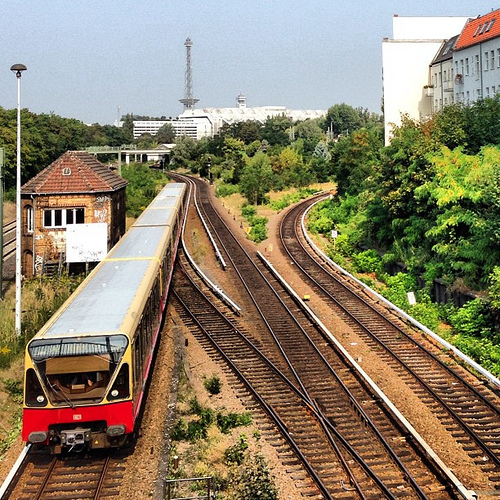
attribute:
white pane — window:
[40, 205, 89, 227]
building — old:
[30, 149, 108, 254]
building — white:
[117, 98, 334, 141]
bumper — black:
[101, 415, 126, 437]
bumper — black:
[103, 423, 130, 442]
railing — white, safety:
[279, 186, 439, 494]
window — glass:
[66, 186, 103, 233]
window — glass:
[30, 360, 137, 402]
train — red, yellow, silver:
[18, 180, 195, 459]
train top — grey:
[36, 225, 168, 336]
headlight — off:
[32, 395, 47, 407]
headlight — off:
[105, 385, 122, 400]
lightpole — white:
[14, 72, 26, 342]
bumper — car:
[25, 430, 49, 450]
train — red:
[1, 282, 131, 447]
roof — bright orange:
[454, 10, 498, 50]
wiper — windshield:
[42, 373, 74, 410]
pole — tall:
[12, 52, 32, 351]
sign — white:
[45, 203, 140, 263]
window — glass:
[35, 204, 55, 232]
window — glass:
[69, 196, 92, 230]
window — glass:
[46, 204, 65, 232]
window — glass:
[56, 201, 78, 233]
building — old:
[429, 2, 484, 116]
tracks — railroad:
[12, 356, 136, 497]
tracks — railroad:
[184, 268, 339, 488]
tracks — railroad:
[254, 263, 417, 498]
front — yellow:
[20, 338, 135, 462]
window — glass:
[147, 290, 164, 328]